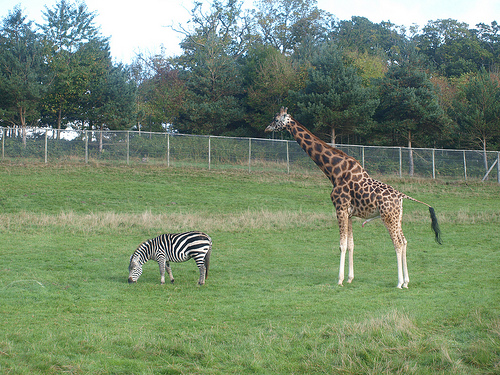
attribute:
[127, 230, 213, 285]
zebra — small, striped, eating, standing, little, grazing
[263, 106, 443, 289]
giraffe — happy, urinating, standing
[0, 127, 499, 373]
enclosure — small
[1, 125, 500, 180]
fence — chain link, long, chain-link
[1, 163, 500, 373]
field — grass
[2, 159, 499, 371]
grass — green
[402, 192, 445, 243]
tail — sticking out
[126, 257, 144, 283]
head — down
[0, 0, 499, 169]
trees — pine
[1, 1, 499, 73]
sky — white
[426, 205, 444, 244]
hair — black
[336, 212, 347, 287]
leg — white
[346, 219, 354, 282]
leg — white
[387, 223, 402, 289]
leg — white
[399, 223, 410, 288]
leg — white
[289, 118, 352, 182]
neck — long